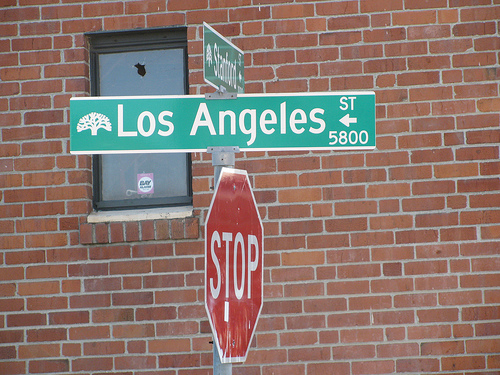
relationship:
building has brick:
[3, 2, 499, 374] [295, 48, 338, 63]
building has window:
[3, 2, 499, 374] [85, 27, 191, 209]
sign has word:
[203, 168, 266, 365] [210, 230, 260, 300]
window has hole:
[85, 27, 191, 209] [134, 63, 146, 78]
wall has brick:
[3, 2, 499, 374] [295, 48, 338, 63]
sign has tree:
[69, 89, 376, 156] [77, 112, 113, 136]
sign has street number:
[69, 89, 376, 156] [328, 129, 368, 147]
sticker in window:
[119, 158, 179, 216] [85, 27, 191, 209]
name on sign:
[75, 85, 439, 175] [69, 89, 376, 156]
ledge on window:
[64, 186, 305, 266] [85, 27, 191, 209]